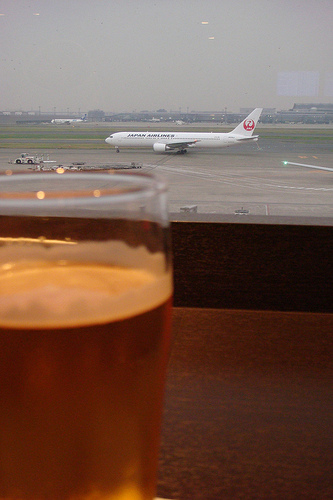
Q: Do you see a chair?
A: No, there are no chairs.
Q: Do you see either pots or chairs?
A: No, there are no chairs or pots.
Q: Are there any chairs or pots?
A: No, there are no chairs or pots.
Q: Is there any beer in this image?
A: Yes, there is beer.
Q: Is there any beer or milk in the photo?
A: Yes, there is beer.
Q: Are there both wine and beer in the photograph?
A: No, there is beer but no wine.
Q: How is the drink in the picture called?
A: The drink is beer.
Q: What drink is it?
A: The drink is beer.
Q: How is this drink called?
A: This is beer.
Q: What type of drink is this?
A: This is beer.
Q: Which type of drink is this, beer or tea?
A: This is beer.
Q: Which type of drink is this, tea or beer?
A: This is beer.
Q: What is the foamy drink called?
A: The drink is beer.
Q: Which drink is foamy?
A: The drink is beer.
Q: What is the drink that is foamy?
A: The drink is beer.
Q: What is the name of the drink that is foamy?
A: The drink is beer.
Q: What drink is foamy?
A: The drink is beer.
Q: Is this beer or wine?
A: This is beer.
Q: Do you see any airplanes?
A: Yes, there is an airplane.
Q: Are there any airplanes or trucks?
A: Yes, there is an airplane.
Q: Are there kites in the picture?
A: No, there are no kites.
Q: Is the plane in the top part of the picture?
A: Yes, the plane is in the top of the image.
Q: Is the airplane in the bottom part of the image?
A: No, the airplane is in the top of the image.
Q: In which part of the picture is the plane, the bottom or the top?
A: The plane is in the top of the image.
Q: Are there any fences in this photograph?
A: No, there are no fences.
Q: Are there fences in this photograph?
A: No, there are no fences.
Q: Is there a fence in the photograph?
A: No, there are no fences.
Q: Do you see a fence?
A: No, there are no fences.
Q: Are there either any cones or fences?
A: No, there are no fences or cones.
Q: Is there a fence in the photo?
A: No, there are no fences.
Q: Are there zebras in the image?
A: No, there are no zebras.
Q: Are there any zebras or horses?
A: No, there are no zebras or horses.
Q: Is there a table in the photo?
A: Yes, there is a table.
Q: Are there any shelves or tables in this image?
A: Yes, there is a table.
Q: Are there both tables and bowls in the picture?
A: No, there is a table but no bowls.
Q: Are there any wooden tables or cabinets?
A: Yes, there is a wood table.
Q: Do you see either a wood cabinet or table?
A: Yes, there is a wood table.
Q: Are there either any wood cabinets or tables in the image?
A: Yes, there is a wood table.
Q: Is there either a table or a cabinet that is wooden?
A: Yes, the table is wooden.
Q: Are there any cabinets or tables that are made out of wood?
A: Yes, the table is made of wood.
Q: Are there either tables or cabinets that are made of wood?
A: Yes, the table is made of wood.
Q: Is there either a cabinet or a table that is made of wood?
A: Yes, the table is made of wood.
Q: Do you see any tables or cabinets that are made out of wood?
A: Yes, the table is made of wood.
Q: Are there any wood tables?
A: Yes, there is a wood table.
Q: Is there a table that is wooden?
A: Yes, there is a table that is wooden.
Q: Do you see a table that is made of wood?
A: Yes, there is a table that is made of wood.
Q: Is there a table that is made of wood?
A: Yes, there is a table that is made of wood.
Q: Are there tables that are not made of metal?
A: Yes, there is a table that is made of wood.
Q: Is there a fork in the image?
A: No, there are no forks.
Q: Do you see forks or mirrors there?
A: No, there are no forks or mirrors.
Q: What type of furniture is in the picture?
A: The furniture is a table.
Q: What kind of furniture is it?
A: The piece of furniture is a table.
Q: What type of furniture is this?
A: This is a table.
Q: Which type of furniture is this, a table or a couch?
A: This is a table.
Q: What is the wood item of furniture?
A: The piece of furniture is a table.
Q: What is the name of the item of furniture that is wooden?
A: The piece of furniture is a table.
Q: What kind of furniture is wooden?
A: The furniture is a table.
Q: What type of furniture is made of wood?
A: The furniture is a table.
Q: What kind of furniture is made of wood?
A: The furniture is a table.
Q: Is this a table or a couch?
A: This is a table.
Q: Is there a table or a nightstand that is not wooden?
A: No, there is a table but it is wooden.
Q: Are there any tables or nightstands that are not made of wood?
A: No, there is a table but it is made of wood.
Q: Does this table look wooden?
A: Yes, the table is wooden.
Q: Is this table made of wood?
A: Yes, the table is made of wood.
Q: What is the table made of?
A: The table is made of wood.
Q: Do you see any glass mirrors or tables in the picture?
A: No, there is a table but it is wooden.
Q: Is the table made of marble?
A: No, the table is made of wood.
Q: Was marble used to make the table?
A: No, the table is made of wood.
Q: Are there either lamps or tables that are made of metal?
A: No, there is a table but it is made of wood.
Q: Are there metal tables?
A: No, there is a table but it is made of wood.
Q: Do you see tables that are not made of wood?
A: No, there is a table but it is made of wood.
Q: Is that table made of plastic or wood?
A: The table is made of wood.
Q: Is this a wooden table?
A: Yes, this is a wooden table.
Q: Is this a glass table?
A: No, this is a wooden table.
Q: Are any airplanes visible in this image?
A: Yes, there is an airplane.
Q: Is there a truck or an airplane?
A: Yes, there is an airplane.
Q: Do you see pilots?
A: No, there are no pilots.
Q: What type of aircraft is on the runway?
A: The aircraft is an airplane.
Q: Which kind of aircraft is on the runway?
A: The aircraft is an airplane.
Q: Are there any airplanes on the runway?
A: Yes, there is an airplane on the runway.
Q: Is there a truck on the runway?
A: No, there is an airplane on the runway.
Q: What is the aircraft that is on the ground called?
A: The aircraft is an airplane.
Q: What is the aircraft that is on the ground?
A: The aircraft is an airplane.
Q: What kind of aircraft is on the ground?
A: The aircraft is an airplane.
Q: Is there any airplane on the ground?
A: Yes, there is an airplane on the ground.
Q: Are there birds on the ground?
A: No, there is an airplane on the ground.